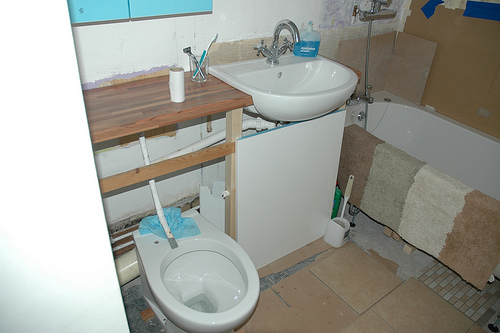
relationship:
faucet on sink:
[260, 18, 303, 67] [206, 52, 358, 122]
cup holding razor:
[189, 56, 207, 83] [184, 44, 205, 82]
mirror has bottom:
[70, 2, 214, 27] [71, 11, 214, 21]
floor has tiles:
[255, 235, 498, 331] [292, 245, 419, 332]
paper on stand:
[166, 68, 187, 105] [82, 64, 259, 140]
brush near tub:
[328, 174, 383, 246] [344, 68, 494, 268]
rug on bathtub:
[360, 128, 498, 275] [346, 94, 500, 286]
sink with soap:
[210, 52, 360, 116] [293, 19, 321, 60]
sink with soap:
[206, 52, 358, 122] [290, 20, 319, 59]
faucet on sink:
[260, 18, 326, 81] [206, 52, 358, 122]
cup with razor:
[191, 56, 207, 85] [181, 39, 198, 70]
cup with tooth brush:
[191, 56, 207, 85] [197, 24, 230, 53]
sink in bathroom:
[206, 52, 358, 122] [53, 2, 496, 330]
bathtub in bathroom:
[346, 94, 498, 249] [78, 4, 473, 310]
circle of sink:
[264, 58, 337, 94] [214, 37, 375, 125]